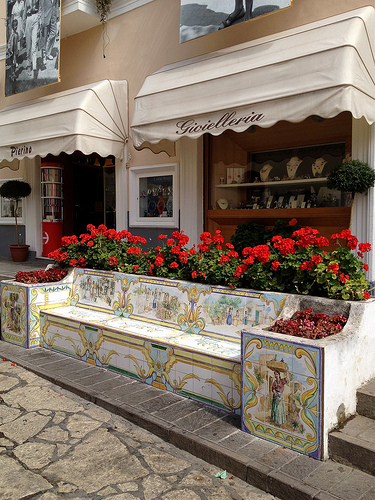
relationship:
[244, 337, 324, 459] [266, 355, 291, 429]
painting shows woman with basket on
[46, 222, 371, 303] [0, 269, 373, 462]
flowers planted in bench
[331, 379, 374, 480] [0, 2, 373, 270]
steps lead to shops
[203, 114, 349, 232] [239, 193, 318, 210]
window displays watches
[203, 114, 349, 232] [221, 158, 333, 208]
window displays jewelry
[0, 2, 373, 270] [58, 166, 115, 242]
shops have entryway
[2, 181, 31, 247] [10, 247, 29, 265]
tree inside pot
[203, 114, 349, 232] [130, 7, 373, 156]
window has awning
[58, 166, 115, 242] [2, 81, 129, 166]
entryway has awning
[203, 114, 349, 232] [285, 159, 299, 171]
window displays necklace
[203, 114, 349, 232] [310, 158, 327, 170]
window d necklace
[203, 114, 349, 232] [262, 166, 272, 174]
window displays necklace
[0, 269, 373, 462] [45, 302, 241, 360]
bench has seat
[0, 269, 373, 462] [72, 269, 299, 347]
bench has back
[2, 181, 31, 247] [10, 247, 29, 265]
tree planted in pot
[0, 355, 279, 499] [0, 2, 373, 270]
street near shops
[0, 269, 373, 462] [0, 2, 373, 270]
bench in front of shops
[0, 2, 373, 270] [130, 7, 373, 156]
shops have awning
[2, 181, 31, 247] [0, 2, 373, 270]
tree in front of shops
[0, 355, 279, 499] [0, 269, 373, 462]
street in front of bench